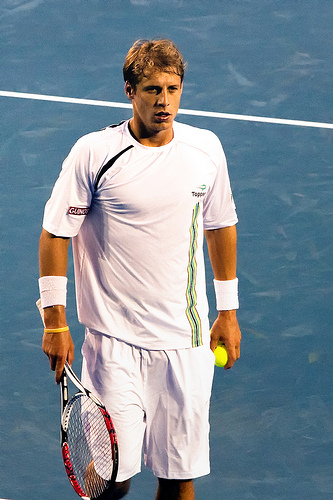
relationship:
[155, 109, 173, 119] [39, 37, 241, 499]
mouth of man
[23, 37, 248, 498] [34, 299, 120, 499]
man holding racket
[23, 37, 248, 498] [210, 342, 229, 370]
man holding tennis ball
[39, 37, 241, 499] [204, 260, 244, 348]
man wearing a wrist band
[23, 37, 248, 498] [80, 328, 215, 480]
man wearing shorts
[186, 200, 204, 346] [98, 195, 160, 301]
rainbow stripe on a shirt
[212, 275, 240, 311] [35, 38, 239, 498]
wrist band being worn by a tennis player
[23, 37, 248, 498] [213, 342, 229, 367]
man playing tennis ball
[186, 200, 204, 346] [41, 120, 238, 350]
rainbow stripe on a white tshirt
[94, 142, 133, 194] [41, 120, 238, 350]
black stripe on a white tshirt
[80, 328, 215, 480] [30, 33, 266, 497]
shorts being worn by player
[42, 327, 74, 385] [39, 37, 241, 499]
hand of a man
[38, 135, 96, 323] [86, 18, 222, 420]
arm of a person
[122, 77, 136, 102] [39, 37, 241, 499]
ear of a man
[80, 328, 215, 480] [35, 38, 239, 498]
shorts on tennis player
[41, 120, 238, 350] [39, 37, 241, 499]
white tshirt on man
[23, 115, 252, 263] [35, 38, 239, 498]
white tshirt on a tennis player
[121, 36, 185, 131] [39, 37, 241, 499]
head on a man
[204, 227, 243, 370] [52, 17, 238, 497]
arm of a person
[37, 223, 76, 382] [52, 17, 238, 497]
arm of a person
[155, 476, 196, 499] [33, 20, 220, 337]
leg of a person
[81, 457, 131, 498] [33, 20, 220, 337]
leg of a person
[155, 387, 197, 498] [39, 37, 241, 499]
leg of a man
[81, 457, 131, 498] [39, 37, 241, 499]
leg of a man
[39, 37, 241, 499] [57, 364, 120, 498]
man holding racket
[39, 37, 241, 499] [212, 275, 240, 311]
man wearing a wrist band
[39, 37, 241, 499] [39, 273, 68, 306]
man wearing a band